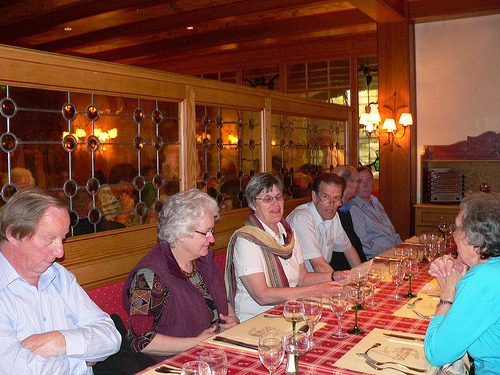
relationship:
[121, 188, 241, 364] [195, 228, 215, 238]
glasses woman has eyeglasses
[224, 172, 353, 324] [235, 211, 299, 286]
woman wears scarf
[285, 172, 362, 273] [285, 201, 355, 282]
man wears shirt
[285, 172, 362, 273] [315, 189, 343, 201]
man wears glasses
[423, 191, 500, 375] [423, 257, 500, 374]
glasses woman wears blue shirt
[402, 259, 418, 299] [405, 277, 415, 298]
wine glass has stem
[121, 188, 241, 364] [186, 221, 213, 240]
glasses woman has eyeglasses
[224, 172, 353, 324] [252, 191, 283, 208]
woman has eyeglasses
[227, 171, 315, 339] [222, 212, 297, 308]
woman has scarf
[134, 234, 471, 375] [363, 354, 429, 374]
dinner table has fork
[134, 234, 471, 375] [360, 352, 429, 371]
dinner table has utensils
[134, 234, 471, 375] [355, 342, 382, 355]
dinner table has utensils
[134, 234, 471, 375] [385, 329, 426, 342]
dinner table has utensils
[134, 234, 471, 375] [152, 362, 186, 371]
dinner table has utensils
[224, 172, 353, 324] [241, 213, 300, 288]
woman has scarf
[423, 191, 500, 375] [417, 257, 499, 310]
glasses woman has hands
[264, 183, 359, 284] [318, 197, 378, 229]
man has face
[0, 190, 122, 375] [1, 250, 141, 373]
man wears shirt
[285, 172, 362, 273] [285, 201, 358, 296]
man wears shirt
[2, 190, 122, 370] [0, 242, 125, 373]
man wears shirt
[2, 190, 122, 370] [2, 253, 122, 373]
man wears shirt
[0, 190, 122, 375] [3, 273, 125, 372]
man wears shirt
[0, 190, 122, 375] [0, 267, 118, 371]
man wears shirt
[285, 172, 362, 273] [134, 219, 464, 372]
man sit at dinner table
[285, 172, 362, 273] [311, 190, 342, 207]
man wears glasses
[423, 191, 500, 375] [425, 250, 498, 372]
glasses woman wears blue shirt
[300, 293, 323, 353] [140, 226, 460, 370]
glass on table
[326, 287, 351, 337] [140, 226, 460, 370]
glass on table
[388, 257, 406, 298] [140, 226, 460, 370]
glass on table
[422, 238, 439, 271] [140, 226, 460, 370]
glass on table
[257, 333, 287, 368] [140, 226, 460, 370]
glass on table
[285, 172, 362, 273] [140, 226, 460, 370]
man at table